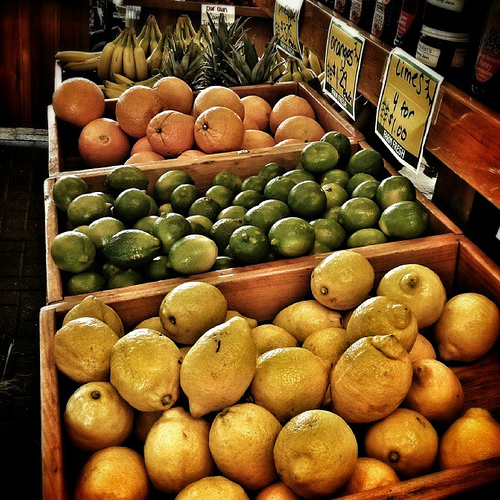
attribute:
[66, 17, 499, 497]
fruit — fresh, five varieties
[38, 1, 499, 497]
bins — wooden, full, four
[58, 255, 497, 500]
lemons — big, shiny, piled, yellow, a bit bungy, extra large, gnarly, burled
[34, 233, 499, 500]
bin — wooden, lemon bin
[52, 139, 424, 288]
limes — large, many shades of green, many shapes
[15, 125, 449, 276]
bin — wooden, lime bin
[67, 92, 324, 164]
oranges — grapefruit size, large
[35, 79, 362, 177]
bin — wooden, orange bin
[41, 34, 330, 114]
bin — wooden, tropical fruit bin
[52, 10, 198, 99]
bananas — tropical fruit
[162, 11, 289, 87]
pineapples — tropical fruit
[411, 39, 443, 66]
label — white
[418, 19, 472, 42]
lid — aluminum, aluminium, screw-on type, white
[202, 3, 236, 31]
sign — paper sign, white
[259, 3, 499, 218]
shelf — wooden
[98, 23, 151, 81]
bananas — four, bunch, minimum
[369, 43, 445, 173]
sign — yellow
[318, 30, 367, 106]
sign — yellow, yellow + black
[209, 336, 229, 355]
line — black, marker-made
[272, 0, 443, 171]
signs — three, framed in white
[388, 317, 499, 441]
bottom — wooden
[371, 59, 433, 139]
writing — black, marker-made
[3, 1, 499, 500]
grocery store — independent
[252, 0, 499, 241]
shelf front — wooden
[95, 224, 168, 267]
lime — long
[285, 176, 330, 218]
lime — round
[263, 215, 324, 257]
lime — round w/ bump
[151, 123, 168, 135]
stem — short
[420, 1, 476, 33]
jar — jam, jelly jar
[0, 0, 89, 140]
wall — wooden